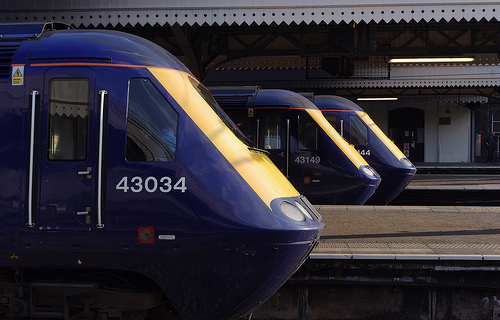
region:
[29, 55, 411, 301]
blue and yellow trains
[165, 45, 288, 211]
yellow stripe on train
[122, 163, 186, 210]
white numbers on train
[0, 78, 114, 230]
grey rails on train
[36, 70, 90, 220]
blue doors on train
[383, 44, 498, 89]
white lights over train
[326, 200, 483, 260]
brown walkway between trains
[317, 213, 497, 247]
long shadow on walkway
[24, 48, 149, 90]
red stripe on train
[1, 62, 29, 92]
yellow and white sticker near door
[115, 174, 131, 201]
white number on train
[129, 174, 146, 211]
white number on train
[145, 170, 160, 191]
white number on train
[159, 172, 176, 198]
white number on train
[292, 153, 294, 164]
white number on train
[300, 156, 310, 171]
white number on train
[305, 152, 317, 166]
white number on train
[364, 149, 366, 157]
white number on train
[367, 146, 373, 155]
white number on train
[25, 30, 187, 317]
this is a train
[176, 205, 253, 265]
the train is blue in color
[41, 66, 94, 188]
this is the door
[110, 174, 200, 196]
this is a writing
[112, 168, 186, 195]
the writing is in white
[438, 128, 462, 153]
the wall is white in color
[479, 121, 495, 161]
this is a man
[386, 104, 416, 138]
this is a door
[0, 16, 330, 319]
Train engine with a pointed nose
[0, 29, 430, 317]
Three adjacent train engines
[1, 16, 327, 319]
Blue painted side of an engine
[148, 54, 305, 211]
Yellow painted front of an engine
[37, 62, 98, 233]
Door to the driver's cabin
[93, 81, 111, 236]
Long white handle on the side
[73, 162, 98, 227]
Pair of door handles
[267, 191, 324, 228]
Round front lights of the engine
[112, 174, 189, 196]
white numbers on blue train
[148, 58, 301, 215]
yellow front of the blue train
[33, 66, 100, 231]
door on the side of the train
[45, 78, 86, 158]
window on the door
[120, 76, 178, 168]
window on the train cockpit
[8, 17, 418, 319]
three blue and yellow trains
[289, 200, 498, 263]
platform between two trains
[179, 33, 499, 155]
building behind train cars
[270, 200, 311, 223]
lights on the front of the train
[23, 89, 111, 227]
bars that door is between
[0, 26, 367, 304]
a blue and yellow train cart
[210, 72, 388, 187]
a blue and yellow train cart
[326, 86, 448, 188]
a blue and yellow train cart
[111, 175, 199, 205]
the numbers 43034 on the train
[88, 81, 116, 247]
a handle on the door to the train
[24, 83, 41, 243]
a handle on the door to the train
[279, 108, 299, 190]
a handle on the door to the train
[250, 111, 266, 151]
a handle on the door to the train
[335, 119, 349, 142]
a handle on the door to the train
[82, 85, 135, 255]
a handle on the door to the train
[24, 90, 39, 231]
handle to assist in boarding a train